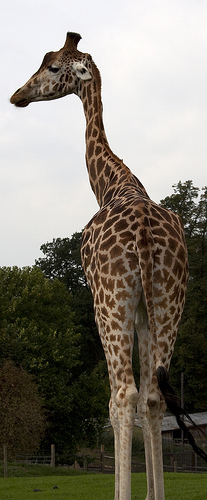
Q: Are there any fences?
A: Yes, there is a fence.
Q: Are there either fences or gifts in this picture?
A: Yes, there is a fence.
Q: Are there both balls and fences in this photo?
A: No, there is a fence but no balls.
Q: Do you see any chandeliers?
A: No, there are no chandeliers.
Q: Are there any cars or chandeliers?
A: No, there are no chandeliers or cars.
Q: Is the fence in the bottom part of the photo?
A: Yes, the fence is in the bottom of the image.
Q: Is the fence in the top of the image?
A: No, the fence is in the bottom of the image.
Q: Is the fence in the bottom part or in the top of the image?
A: The fence is in the bottom of the image.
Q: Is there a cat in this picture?
A: No, there are no cats.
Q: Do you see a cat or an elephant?
A: No, there are no cats or elephants.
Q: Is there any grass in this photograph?
A: Yes, there is grass.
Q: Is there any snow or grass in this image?
A: Yes, there is grass.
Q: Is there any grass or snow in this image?
A: Yes, there is grass.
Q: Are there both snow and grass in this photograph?
A: No, there is grass but no snow.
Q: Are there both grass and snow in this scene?
A: No, there is grass but no snow.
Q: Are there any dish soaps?
A: No, there are no dish soaps.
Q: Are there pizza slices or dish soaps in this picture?
A: No, there are no dish soaps or pizza slices.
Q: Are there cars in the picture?
A: No, there are no cars.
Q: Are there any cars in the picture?
A: No, there are no cars.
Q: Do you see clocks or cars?
A: No, there are no cars or clocks.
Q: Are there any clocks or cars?
A: No, there are no cars or clocks.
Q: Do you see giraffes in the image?
A: Yes, there is a giraffe.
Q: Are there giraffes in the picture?
A: Yes, there is a giraffe.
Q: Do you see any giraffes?
A: Yes, there is a giraffe.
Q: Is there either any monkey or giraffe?
A: Yes, there is a giraffe.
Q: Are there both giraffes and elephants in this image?
A: No, there is a giraffe but no elephants.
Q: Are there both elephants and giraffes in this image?
A: No, there is a giraffe but no elephants.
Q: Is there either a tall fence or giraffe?
A: Yes, there is a tall giraffe.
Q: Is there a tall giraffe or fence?
A: Yes, there is a tall giraffe.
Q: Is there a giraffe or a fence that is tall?
A: Yes, the giraffe is tall.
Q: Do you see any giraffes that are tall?
A: Yes, there is a tall giraffe.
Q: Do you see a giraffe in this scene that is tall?
A: Yes, there is a giraffe that is tall.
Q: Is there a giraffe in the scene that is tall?
A: Yes, there is a giraffe that is tall.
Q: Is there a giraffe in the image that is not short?
A: Yes, there is a tall giraffe.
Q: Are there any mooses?
A: No, there are no mooses.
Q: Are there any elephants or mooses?
A: No, there are no mooses or elephants.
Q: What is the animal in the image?
A: The animal is a giraffe.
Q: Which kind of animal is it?
A: The animal is a giraffe.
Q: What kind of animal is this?
A: This is a giraffe.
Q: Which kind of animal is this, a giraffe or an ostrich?
A: This is a giraffe.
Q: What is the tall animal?
A: The animal is a giraffe.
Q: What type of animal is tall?
A: The animal is a giraffe.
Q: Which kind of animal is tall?
A: The animal is a giraffe.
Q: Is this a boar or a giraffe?
A: This is a giraffe.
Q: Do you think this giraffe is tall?
A: Yes, the giraffe is tall.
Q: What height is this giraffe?
A: The giraffe is tall.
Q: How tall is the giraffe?
A: The giraffe is tall.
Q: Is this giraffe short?
A: No, the giraffe is tall.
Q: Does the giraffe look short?
A: No, the giraffe is tall.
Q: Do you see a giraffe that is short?
A: No, there is a giraffe but it is tall.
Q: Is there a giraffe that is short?
A: No, there is a giraffe but it is tall.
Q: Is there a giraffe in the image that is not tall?
A: No, there is a giraffe but it is tall.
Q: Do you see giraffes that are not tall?
A: No, there is a giraffe but it is tall.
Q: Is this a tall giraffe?
A: Yes, this is a tall giraffe.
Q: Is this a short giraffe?
A: No, this is a tall giraffe.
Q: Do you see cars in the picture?
A: No, there are no cars.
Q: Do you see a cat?
A: No, there are no cats.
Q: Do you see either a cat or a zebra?
A: No, there are no cats or zebras.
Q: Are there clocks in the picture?
A: No, there are no clocks.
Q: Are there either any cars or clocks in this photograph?
A: No, there are no clocks or cars.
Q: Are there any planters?
A: No, there are no planters.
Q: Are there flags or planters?
A: No, there are no planters or flags.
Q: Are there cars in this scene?
A: No, there are no cars.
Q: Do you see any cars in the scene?
A: No, there are no cars.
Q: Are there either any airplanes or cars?
A: No, there are no cars or airplanes.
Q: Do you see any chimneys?
A: No, there are no chimneys.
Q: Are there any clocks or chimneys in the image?
A: No, there are no chimneys or clocks.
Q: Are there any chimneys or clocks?
A: No, there are no chimneys or clocks.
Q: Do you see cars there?
A: No, there are no cars.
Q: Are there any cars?
A: No, there are no cars.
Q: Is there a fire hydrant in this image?
A: No, there are no fire hydrants.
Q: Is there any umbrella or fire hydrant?
A: No, there are no fire hydrants or umbrellas.